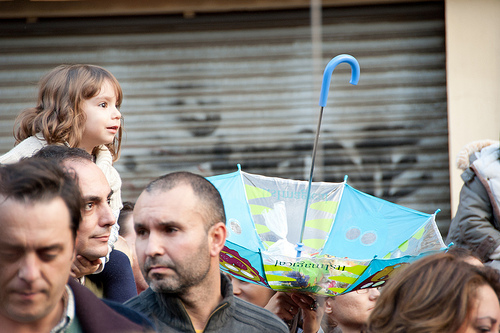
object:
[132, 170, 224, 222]
head shaved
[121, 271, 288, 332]
sweater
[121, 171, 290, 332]
human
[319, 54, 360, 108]
blue handle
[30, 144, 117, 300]
man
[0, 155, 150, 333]
man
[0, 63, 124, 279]
child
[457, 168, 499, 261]
sleeve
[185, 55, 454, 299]
umbrella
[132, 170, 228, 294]
man hair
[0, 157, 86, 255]
hair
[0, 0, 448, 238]
door